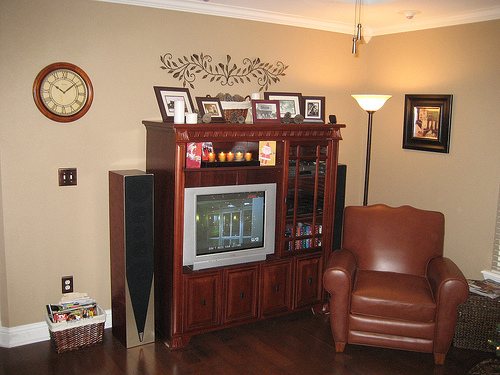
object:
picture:
[410, 103, 441, 143]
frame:
[398, 90, 455, 155]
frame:
[28, 60, 99, 125]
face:
[42, 70, 85, 114]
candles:
[204, 150, 218, 160]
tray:
[203, 158, 258, 168]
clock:
[32, 60, 98, 125]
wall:
[6, 0, 368, 347]